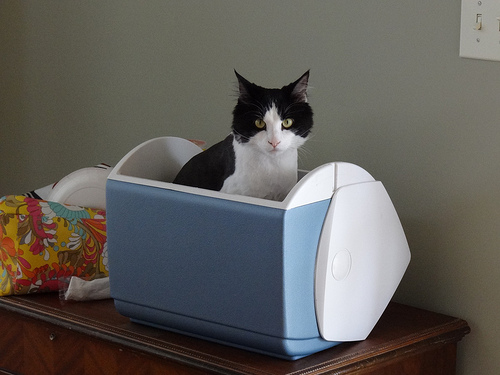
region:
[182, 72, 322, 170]
this is a cat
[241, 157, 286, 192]
the cat is white in color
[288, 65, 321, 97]
this is the ear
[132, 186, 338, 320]
the cat is in a container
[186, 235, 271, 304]
the container is blue in color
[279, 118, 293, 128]
the eye is open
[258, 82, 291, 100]
the head is black in color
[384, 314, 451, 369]
this is a stand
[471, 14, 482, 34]
this is a switch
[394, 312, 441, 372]
the stand is wooden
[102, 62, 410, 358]
a cat in a cooler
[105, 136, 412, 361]
a blue and white cooler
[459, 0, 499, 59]
light switch on a wall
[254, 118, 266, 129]
the eye of a cat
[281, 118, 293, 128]
the eye of a cat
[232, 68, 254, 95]
a cat's ear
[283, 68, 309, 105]
a cat's ear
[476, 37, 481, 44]
bolt on a light switch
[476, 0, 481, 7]
screw head on a light switch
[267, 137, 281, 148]
nose of a cat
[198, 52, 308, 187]
A black and white cat.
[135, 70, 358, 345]
A cat sitting in a blue and white cooler.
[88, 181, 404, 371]
A cooler sitting on top of a brown wooden stand.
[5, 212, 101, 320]
A floral bag sitting on top of a wooden stand.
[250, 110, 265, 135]
The cat has green eyes.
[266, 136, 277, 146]
A cat with a pink nose.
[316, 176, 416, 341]
The white cover of the cooler.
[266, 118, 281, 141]
The cat has white fur on its nose.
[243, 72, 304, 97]
The cat has black fur on its ears.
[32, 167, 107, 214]
Items sticking out of a floral bag.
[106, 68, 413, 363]
black and white cat sitting in a cooler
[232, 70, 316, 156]
head of black and white cat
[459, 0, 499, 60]
wall light switch to the right of the cat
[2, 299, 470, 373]
furniture the cooler is sitting on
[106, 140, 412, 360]
cooler the cat is sitting in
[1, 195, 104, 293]
multicolored patterned fabric to the left of the cooler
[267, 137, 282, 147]
the black and white cat's nose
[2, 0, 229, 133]
part of wall to the left of the cat's head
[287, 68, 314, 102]
ear of black and white cat's that is closest to wall switch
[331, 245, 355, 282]
circle on the white part of cooler's lid on right side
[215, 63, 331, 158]
Lovely black and white cat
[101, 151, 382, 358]
Blue and white cooler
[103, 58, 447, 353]
Cat sitting in cooler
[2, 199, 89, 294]
Brightly colored bag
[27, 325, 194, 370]
Dark brown wood grain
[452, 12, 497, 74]
White light switch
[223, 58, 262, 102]
Black ear of an kitten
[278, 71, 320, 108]
Black and pink ear of a kitten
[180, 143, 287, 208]
Black and white body of a kitten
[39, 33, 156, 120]
Very lovely painted walls